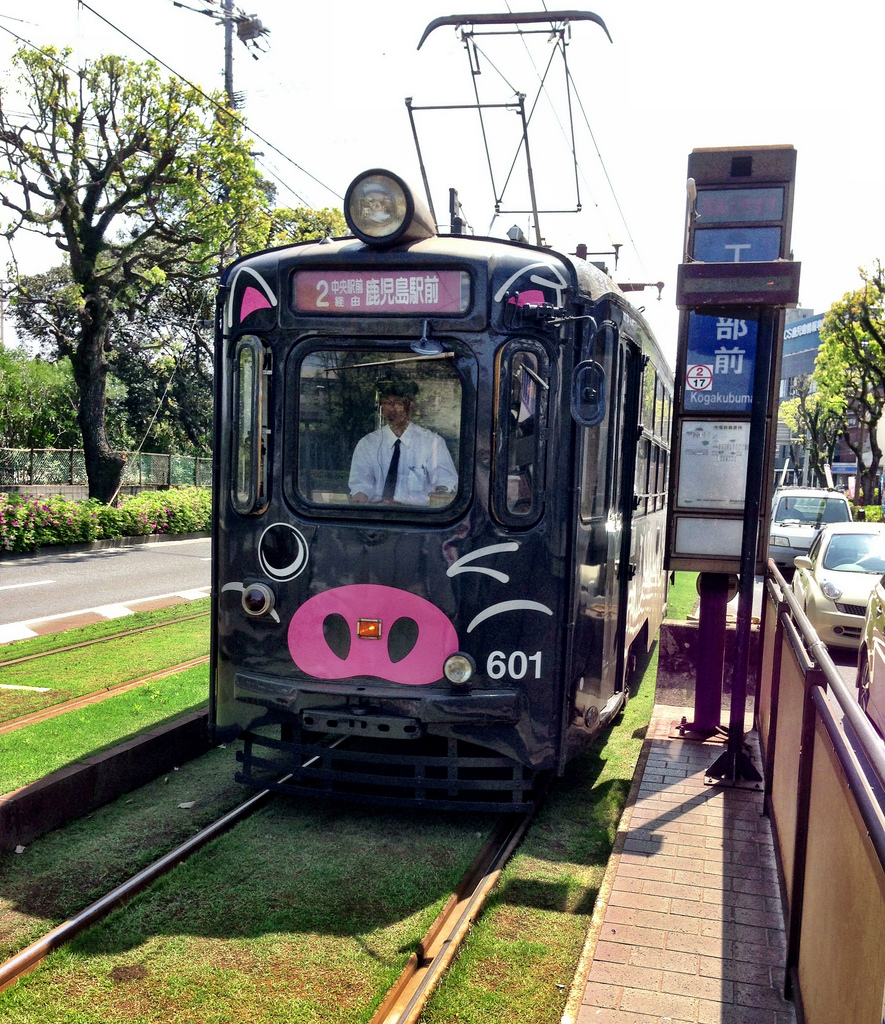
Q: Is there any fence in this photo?
A: Yes, there is a fence.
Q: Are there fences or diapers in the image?
A: Yes, there is a fence.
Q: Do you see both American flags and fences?
A: No, there is a fence but no American flags.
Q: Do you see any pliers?
A: No, there are no pliers.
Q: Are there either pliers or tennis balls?
A: No, there are no pliers or tennis balls.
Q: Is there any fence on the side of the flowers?
A: Yes, there is a fence on the side of the flowers.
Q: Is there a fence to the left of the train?
A: Yes, there is a fence to the left of the train.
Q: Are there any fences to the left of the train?
A: Yes, there is a fence to the left of the train.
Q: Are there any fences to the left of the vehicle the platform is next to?
A: Yes, there is a fence to the left of the train.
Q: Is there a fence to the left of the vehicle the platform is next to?
A: Yes, there is a fence to the left of the train.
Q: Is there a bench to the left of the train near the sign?
A: No, there is a fence to the left of the train.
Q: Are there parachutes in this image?
A: No, there are no parachutes.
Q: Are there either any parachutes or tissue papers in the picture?
A: No, there are no parachutes or tissue papers.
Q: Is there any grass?
A: Yes, there is grass.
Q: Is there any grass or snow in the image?
A: Yes, there is grass.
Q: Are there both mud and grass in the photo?
A: No, there is grass but no mud.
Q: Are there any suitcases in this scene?
A: No, there are no suitcases.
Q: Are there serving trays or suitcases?
A: No, there are no suitcases or serving trays.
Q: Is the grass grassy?
A: Yes, the grass is grassy.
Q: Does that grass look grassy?
A: Yes, the grass is grassy.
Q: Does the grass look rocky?
A: No, the grass is grassy.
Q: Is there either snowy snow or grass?
A: No, there is grass but it is grassy.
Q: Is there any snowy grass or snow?
A: No, there is grass but it is grassy.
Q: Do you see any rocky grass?
A: No, there is grass but it is grassy.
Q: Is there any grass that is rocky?
A: No, there is grass but it is grassy.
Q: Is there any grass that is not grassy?
A: No, there is grass but it is grassy.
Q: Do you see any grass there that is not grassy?
A: No, there is grass but it is grassy.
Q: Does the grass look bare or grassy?
A: The grass is grassy.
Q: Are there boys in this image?
A: No, there are no boys.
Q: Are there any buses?
A: No, there are no buses.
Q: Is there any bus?
A: No, there are no buses.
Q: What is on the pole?
A: The sign is on the pole.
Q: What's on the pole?
A: The sign is on the pole.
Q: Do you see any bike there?
A: No, there are no bikes.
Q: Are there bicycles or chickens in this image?
A: No, there are no bicycles or chickens.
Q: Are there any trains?
A: Yes, there is a train.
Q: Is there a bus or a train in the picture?
A: Yes, there is a train.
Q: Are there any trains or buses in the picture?
A: Yes, there is a train.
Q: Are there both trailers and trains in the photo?
A: No, there is a train but no trailers.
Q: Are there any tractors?
A: No, there are no tractors.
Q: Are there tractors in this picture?
A: No, there are no tractors.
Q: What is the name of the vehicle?
A: The vehicle is a train.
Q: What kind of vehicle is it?
A: The vehicle is a train.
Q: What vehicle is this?
A: That is a train.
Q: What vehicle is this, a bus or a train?
A: That is a train.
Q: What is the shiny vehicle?
A: The vehicle is a train.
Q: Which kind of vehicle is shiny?
A: The vehicle is a train.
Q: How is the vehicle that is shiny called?
A: The vehicle is a train.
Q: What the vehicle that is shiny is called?
A: The vehicle is a train.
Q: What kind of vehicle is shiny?
A: The vehicle is a train.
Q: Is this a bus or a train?
A: This is a train.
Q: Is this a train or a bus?
A: This is a train.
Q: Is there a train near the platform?
A: Yes, there is a train near the platform.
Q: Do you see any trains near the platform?
A: Yes, there is a train near the platform.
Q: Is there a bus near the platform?
A: No, there is a train near the platform.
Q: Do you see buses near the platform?
A: No, there is a train near the platform.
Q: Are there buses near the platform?
A: No, there is a train near the platform.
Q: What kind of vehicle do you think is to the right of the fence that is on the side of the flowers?
A: The vehicle is a train.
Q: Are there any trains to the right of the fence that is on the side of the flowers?
A: Yes, there is a train to the right of the fence.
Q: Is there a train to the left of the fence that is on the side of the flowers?
A: No, the train is to the right of the fence.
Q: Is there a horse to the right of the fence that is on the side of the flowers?
A: No, there is a train to the right of the fence.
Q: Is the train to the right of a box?
A: No, the train is to the right of a fence.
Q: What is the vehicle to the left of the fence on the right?
A: The vehicle is a train.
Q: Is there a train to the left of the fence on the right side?
A: Yes, there is a train to the left of the fence.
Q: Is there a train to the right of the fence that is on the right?
A: No, the train is to the left of the fence.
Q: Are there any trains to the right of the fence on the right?
A: No, the train is to the left of the fence.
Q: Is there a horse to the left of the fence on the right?
A: No, there is a train to the left of the fence.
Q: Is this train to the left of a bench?
A: No, the train is to the left of the fence.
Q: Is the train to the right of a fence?
A: No, the train is to the left of a fence.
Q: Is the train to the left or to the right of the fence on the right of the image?
A: The train is to the left of the fence.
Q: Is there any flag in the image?
A: No, there are no flags.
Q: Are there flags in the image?
A: No, there are no flags.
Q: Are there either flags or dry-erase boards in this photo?
A: No, there are no flags or dry-erase boards.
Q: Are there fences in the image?
A: Yes, there is a fence.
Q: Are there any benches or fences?
A: Yes, there is a fence.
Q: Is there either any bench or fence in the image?
A: Yes, there is a fence.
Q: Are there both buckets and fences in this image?
A: No, there is a fence but no buckets.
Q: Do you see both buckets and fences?
A: No, there is a fence but no buckets.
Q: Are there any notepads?
A: No, there are no notepads.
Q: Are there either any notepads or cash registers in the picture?
A: No, there are no notepads or cash registers.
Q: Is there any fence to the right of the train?
A: Yes, there is a fence to the right of the train.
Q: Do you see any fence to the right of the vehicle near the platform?
A: Yes, there is a fence to the right of the train.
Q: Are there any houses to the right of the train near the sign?
A: No, there is a fence to the right of the train.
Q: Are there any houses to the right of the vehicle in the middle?
A: No, there is a fence to the right of the train.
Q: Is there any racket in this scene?
A: No, there are no rackets.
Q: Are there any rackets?
A: No, there are no rackets.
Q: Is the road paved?
A: Yes, the road is paved.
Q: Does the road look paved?
A: Yes, the road is paved.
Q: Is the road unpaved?
A: No, the road is paved.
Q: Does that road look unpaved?
A: No, the road is paved.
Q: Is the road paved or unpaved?
A: The road is paved.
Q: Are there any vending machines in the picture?
A: No, there are no vending machines.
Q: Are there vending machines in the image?
A: No, there are no vending machines.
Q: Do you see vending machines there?
A: No, there are no vending machines.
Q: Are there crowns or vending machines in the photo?
A: No, there are no vending machines or crowns.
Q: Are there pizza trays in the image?
A: No, there are no pizza trays.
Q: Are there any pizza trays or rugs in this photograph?
A: No, there are no pizza trays or rugs.